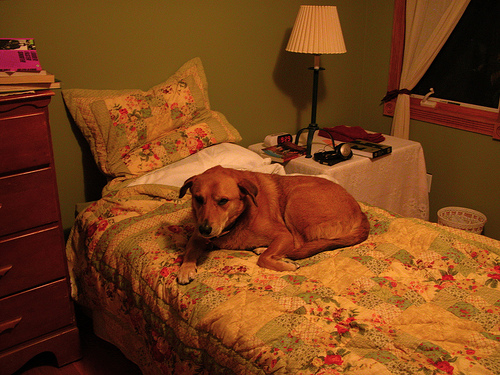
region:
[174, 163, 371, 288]
A brown dog laying on a bed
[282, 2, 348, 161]
A desk lamp with a white cover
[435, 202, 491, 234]
The top of a white plastic trash can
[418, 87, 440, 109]
A white handle on the window sill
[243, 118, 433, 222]
A bedside table with a white covering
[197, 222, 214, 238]
The black nose of the dog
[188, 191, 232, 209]
The eyes of the dog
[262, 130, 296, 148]
A white alram clock on the table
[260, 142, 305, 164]
A book on the table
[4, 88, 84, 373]
A brown chest of drawers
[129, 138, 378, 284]
dog on the bed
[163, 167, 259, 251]
head of the dog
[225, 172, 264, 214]
ear of the dog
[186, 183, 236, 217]
eyes of the dog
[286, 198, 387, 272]
tail of the dog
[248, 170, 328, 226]
brown fur on dog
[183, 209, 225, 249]
nose of the dog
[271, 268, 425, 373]
flowers on the bed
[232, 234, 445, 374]
blanket on the bed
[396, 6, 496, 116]
a window on the wall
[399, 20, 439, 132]
a white curtain on the wall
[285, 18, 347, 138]
a lamp on the table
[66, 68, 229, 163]
a pillow on the bed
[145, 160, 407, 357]
a dog laying on a bed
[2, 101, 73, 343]
a wooden dresser next to the bed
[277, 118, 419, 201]
a small table next to the bed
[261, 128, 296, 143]
an alarm clock on the table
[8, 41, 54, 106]
books on top of the dresser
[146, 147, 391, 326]
a dog on a bed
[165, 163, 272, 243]
head of a dog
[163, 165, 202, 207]
ear of a dog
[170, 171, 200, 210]
an ear of a dog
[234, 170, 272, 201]
an ear of a dog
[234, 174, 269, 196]
ear of a dog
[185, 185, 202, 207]
eye of a dog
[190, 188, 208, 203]
an eye of a dog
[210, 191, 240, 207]
eye of a dog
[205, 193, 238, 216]
an eye of a dog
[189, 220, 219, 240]
nose of a dog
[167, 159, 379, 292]
Dog on the bed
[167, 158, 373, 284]
Dog is on the bed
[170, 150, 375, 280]
Dog laying on the bed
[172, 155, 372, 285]
Dog is laying on the bed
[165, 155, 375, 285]
Brown dog on the bed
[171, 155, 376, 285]
Brown dog is on the bed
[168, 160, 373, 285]
Brown dog laying on the bed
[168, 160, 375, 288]
Brown dog is laying on the bed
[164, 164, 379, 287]
Brown dog on top of bed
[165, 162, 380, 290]
Brown dog is on top of bed